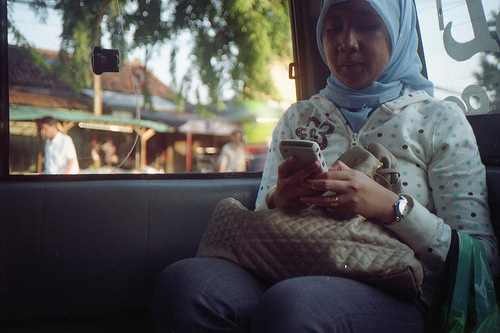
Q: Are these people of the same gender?
A: No, they are both male and female.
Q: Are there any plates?
A: No, there are no plates.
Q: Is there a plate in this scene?
A: No, there are no plates.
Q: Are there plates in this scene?
A: No, there are no plates.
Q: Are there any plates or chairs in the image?
A: No, there are no plates or chairs.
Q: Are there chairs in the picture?
A: No, there are no chairs.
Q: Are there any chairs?
A: No, there are no chairs.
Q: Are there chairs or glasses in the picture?
A: No, there are no chairs or glasses.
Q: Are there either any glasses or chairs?
A: No, there are no chairs or glasses.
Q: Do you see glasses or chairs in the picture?
A: No, there are no chairs or glasses.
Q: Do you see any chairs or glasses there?
A: No, there are no chairs or glasses.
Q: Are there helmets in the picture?
A: No, there are no helmets.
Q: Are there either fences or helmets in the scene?
A: No, there are no helmets or fences.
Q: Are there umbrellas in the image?
A: Yes, there is an umbrella.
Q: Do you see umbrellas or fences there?
A: Yes, there is an umbrella.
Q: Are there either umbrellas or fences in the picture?
A: Yes, there is an umbrella.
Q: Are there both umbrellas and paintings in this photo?
A: No, there is an umbrella but no paintings.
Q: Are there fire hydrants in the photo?
A: No, there are no fire hydrants.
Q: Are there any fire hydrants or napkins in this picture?
A: No, there are no fire hydrants or napkins.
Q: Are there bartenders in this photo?
A: No, there are no bartenders.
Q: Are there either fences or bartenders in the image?
A: No, there are no bartenders or fences.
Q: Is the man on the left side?
A: Yes, the man is on the left of the image.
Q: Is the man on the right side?
A: No, the man is on the left of the image.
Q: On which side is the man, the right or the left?
A: The man is on the left of the image.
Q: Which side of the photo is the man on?
A: The man is on the left of the image.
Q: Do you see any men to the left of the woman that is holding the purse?
A: Yes, there is a man to the left of the woman.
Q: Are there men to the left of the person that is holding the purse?
A: Yes, there is a man to the left of the woman.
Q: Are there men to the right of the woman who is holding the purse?
A: No, the man is to the left of the woman.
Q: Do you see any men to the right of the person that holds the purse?
A: No, the man is to the left of the woman.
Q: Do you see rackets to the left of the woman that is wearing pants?
A: No, there is a man to the left of the woman.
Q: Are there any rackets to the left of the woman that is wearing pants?
A: No, there is a man to the left of the woman.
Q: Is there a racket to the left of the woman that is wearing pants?
A: No, there is a man to the left of the woman.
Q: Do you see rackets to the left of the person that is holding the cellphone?
A: No, there is a man to the left of the woman.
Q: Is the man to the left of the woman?
A: Yes, the man is to the left of the woman.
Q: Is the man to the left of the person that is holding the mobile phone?
A: Yes, the man is to the left of the woman.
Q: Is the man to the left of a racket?
A: No, the man is to the left of the woman.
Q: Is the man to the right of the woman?
A: No, the man is to the left of the woman.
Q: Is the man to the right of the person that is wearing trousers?
A: No, the man is to the left of the woman.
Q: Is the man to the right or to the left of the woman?
A: The man is to the left of the woman.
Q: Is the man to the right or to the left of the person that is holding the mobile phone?
A: The man is to the left of the woman.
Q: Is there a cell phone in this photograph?
A: Yes, there is a cell phone.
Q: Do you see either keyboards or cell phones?
A: Yes, there is a cell phone.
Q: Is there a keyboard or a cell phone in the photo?
A: Yes, there is a cell phone.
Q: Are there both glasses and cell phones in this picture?
A: No, there is a cell phone but no glasses.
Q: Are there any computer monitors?
A: No, there are no computer monitors.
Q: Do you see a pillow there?
A: No, there are no pillows.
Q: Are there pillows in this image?
A: No, there are no pillows.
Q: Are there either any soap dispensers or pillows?
A: No, there are no pillows or soap dispensers.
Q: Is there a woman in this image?
A: Yes, there is a woman.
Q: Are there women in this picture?
A: Yes, there is a woman.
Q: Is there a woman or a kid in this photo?
A: Yes, there is a woman.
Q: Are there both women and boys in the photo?
A: No, there is a woman but no boys.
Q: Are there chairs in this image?
A: No, there are no chairs.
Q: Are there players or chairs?
A: No, there are no chairs or players.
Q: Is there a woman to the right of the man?
A: Yes, there is a woman to the right of the man.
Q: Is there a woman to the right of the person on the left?
A: Yes, there is a woman to the right of the man.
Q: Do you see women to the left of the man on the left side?
A: No, the woman is to the right of the man.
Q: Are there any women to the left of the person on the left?
A: No, the woman is to the right of the man.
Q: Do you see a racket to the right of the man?
A: No, there is a woman to the right of the man.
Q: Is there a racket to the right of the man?
A: No, there is a woman to the right of the man.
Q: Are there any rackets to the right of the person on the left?
A: No, there is a woman to the right of the man.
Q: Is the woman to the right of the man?
A: Yes, the woman is to the right of the man.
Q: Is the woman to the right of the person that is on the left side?
A: Yes, the woman is to the right of the man.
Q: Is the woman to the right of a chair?
A: No, the woman is to the right of the man.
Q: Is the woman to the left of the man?
A: No, the woman is to the right of the man.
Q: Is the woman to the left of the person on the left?
A: No, the woman is to the right of the man.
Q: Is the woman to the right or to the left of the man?
A: The woman is to the right of the man.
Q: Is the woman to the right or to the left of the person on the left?
A: The woman is to the right of the man.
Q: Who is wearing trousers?
A: The woman is wearing trousers.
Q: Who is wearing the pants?
A: The woman is wearing trousers.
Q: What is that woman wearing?
A: The woman is wearing pants.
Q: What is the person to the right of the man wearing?
A: The woman is wearing pants.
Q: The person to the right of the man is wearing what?
A: The woman is wearing pants.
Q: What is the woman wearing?
A: The woman is wearing pants.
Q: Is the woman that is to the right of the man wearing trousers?
A: Yes, the woman is wearing trousers.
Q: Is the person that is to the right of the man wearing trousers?
A: Yes, the woman is wearing trousers.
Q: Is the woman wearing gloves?
A: No, the woman is wearing trousers.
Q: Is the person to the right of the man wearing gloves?
A: No, the woman is wearing trousers.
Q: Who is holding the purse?
A: The woman is holding the purse.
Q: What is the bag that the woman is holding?
A: The bag is a purse.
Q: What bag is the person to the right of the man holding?
A: The woman is holding the purse.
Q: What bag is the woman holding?
A: The woman is holding the purse.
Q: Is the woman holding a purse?
A: Yes, the woman is holding a purse.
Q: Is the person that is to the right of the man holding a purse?
A: Yes, the woman is holding a purse.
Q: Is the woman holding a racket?
A: No, the woman is holding a purse.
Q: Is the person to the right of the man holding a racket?
A: No, the woman is holding a purse.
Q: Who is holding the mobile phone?
A: The woman is holding the mobile phone.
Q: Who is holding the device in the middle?
A: The woman is holding the mobile phone.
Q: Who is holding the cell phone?
A: The woman is holding the mobile phone.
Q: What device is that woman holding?
A: The woman is holding the cell phone.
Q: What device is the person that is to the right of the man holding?
A: The woman is holding the cell phone.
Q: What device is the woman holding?
A: The woman is holding the cell phone.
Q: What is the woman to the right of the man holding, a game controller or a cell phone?
A: The woman is holding a cell phone.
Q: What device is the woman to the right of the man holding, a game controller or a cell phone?
A: The woman is holding a cell phone.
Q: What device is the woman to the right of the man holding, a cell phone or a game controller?
A: The woman is holding a cell phone.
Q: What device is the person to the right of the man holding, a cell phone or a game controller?
A: The woman is holding a cell phone.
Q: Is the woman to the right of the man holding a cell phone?
A: Yes, the woman is holding a cell phone.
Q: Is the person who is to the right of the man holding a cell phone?
A: Yes, the woman is holding a cell phone.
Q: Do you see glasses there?
A: No, there are no glasses.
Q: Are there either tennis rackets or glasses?
A: No, there are no glasses or tennis rackets.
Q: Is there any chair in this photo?
A: No, there are no chairs.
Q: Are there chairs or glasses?
A: No, there are no chairs or glasses.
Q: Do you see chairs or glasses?
A: No, there are no chairs or glasses.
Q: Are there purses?
A: Yes, there is a purse.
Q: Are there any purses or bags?
A: Yes, there is a purse.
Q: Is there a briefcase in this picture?
A: No, there are no briefcases.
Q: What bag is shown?
A: The bag is a purse.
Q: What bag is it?
A: The bag is a purse.